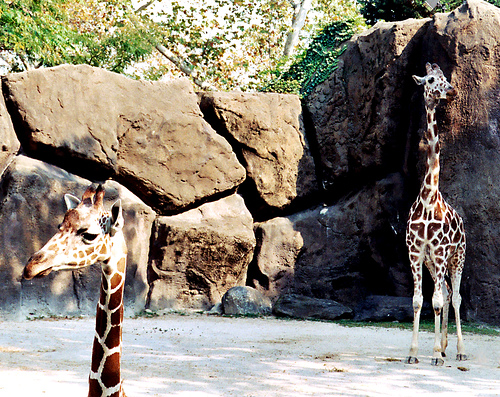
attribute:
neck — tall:
[90, 263, 125, 395]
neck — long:
[423, 102, 442, 192]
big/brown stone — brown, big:
[200, 91, 320, 212]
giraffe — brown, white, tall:
[403, 59, 470, 367]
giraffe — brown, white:
[19, 183, 130, 395]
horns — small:
[80, 190, 101, 207]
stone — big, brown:
[248, 169, 406, 296]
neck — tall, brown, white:
[421, 104, 462, 205]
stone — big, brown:
[5, 63, 246, 208]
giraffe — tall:
[370, 74, 496, 234]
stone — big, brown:
[10, 18, 330, 221]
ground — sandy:
[281, 335, 344, 372]